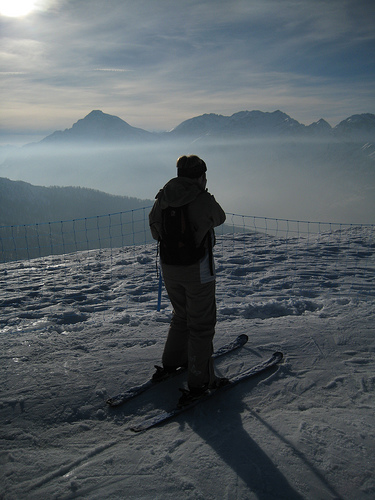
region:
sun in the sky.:
[0, 0, 56, 27]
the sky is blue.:
[2, 1, 374, 124]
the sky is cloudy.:
[4, 0, 374, 124]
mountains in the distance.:
[3, 99, 373, 150]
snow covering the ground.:
[0, 222, 373, 490]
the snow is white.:
[0, 225, 373, 497]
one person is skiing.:
[100, 144, 296, 429]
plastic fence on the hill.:
[2, 192, 370, 306]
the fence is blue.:
[2, 198, 373, 303]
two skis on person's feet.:
[102, 320, 280, 435]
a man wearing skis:
[103, 323, 298, 439]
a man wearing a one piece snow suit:
[141, 159, 239, 385]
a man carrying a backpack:
[140, 195, 212, 282]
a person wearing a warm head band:
[169, 165, 222, 180]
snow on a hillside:
[2, 228, 374, 499]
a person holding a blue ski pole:
[139, 223, 170, 309]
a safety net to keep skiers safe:
[0, 207, 354, 252]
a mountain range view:
[1, 102, 371, 213]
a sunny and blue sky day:
[0, 0, 366, 247]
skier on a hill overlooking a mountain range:
[26, 103, 374, 437]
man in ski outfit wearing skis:
[128, 196, 247, 400]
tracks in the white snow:
[19, 403, 109, 470]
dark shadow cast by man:
[203, 377, 311, 489]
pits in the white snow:
[240, 240, 342, 333]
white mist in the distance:
[230, 99, 359, 194]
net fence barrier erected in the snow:
[253, 181, 373, 310]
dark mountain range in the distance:
[30, 96, 373, 152]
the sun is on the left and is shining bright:
[9, 1, 63, 52]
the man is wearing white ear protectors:
[169, 161, 206, 181]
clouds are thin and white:
[13, 36, 163, 122]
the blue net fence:
[0, 200, 373, 266]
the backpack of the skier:
[152, 200, 215, 274]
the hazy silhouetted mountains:
[13, 101, 374, 217]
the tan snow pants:
[141, 281, 236, 385]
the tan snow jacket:
[143, 174, 228, 287]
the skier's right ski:
[126, 346, 296, 466]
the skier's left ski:
[107, 324, 274, 409]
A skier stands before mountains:
[96, 148, 290, 453]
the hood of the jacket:
[147, 174, 203, 207]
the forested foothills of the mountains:
[3, 175, 253, 256]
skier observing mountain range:
[134, 151, 286, 421]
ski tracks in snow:
[11, 416, 209, 496]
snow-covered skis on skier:
[106, 328, 291, 432]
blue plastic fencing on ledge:
[1, 200, 372, 319]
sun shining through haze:
[2, 1, 60, 26]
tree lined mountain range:
[2, 172, 243, 263]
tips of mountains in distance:
[23, 97, 372, 152]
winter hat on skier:
[171, 148, 203, 178]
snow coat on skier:
[145, 168, 235, 266]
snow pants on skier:
[153, 243, 222, 382]